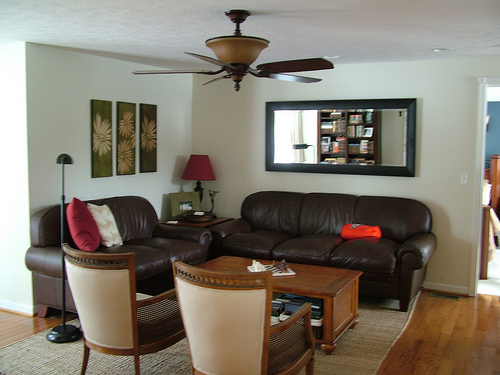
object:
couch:
[26, 195, 211, 319]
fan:
[128, 9, 334, 92]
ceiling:
[0, 0, 499, 70]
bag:
[338, 221, 384, 242]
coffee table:
[183, 253, 364, 356]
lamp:
[179, 153, 218, 211]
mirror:
[263, 97, 418, 179]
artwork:
[87, 98, 114, 180]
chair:
[168, 256, 320, 371]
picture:
[138, 101, 158, 174]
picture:
[113, 100, 138, 176]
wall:
[24, 42, 194, 231]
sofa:
[210, 190, 437, 311]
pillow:
[85, 202, 124, 249]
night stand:
[154, 210, 236, 229]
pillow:
[63, 195, 102, 253]